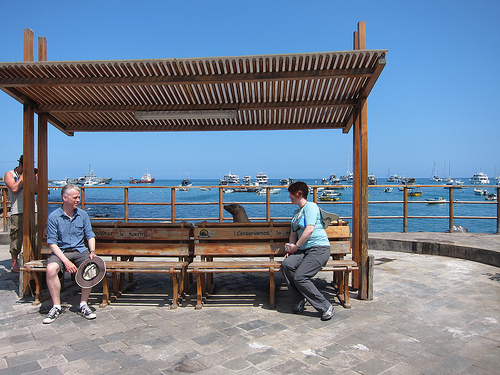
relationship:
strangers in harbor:
[5, 153, 335, 324] [1, 179, 497, 372]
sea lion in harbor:
[224, 204, 251, 223] [1, 179, 497, 372]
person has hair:
[281, 181, 335, 320] [288, 180, 310, 199]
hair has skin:
[288, 180, 310, 199] [285, 189, 313, 252]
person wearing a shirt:
[281, 181, 335, 320] [290, 200, 330, 249]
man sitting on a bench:
[4, 155, 38, 273] [22, 219, 371, 305]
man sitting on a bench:
[42, 184, 106, 324] [22, 219, 371, 305]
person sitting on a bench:
[283, 179, 335, 321] [22, 219, 371, 305]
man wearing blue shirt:
[42, 184, 106, 324] [47, 207, 96, 256]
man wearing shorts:
[42, 184, 106, 324] [49, 248, 91, 270]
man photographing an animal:
[12, 151, 37, 301] [222, 203, 251, 221]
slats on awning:
[0, 49, 389, 133] [0, 49, 388, 137]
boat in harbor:
[124, 168, 171, 189] [1, 179, 497, 372]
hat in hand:
[72, 253, 107, 290] [86, 252, 97, 260]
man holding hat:
[42, 184, 106, 324] [72, 253, 107, 290]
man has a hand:
[42, 184, 106, 324] [86, 252, 97, 260]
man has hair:
[35, 175, 110, 328] [57, 177, 82, 197]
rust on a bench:
[25, 219, 192, 306] [21, 220, 196, 308]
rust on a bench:
[188, 220, 357, 310] [187, 216, 361, 308]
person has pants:
[281, 181, 335, 320] [282, 247, 327, 302]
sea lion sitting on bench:
[216, 197, 258, 229] [189, 223, 270, 276]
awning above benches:
[1, 60, 378, 129] [42, 221, 353, 285]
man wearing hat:
[42, 184, 106, 324] [9, 152, 39, 174]